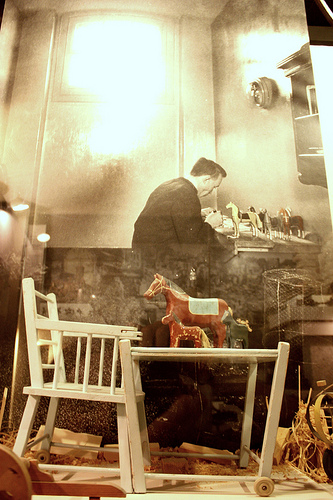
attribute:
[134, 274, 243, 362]
horse — wooden, wood, toy, white, baby, many, fake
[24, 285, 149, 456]
chair — wooden, white, wood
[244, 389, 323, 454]
wire — basket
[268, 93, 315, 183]
window — light, store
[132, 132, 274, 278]
man — carving, painting, working, sitting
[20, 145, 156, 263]
wall — attached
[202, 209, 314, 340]
table — wood, support, white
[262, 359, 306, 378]
wheel — tan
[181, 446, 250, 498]
floor — wood, wooden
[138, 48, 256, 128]
sun — shining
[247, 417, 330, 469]
basket — metal, small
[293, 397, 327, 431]
net — metal